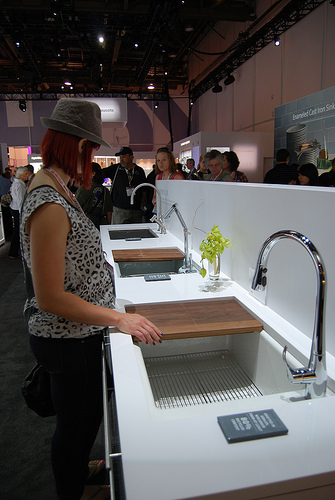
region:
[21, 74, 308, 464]
people standing among displays at convention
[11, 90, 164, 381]
woman leaning against white counter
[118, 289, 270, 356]
hand on wooden cutting board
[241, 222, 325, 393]
neck of curved silver faucet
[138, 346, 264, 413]
metal grid at bottom of sink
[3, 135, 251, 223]
convention attendees close together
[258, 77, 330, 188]
people in front of large poster on wall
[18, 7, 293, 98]
lights and supporting structures on ceiling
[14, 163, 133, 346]
woman in animal-print blouse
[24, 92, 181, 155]
lighted panel on elevated wall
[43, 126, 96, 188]
bold red hair on a woman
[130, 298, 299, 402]
an open sink display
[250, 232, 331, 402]
a large curved metal sink faucet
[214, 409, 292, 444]
a grey and white book on the counter top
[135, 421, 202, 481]
the white sink display counter top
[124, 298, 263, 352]
the woman's hand resting on a wooden sliding block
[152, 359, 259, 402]
a metal draining board in the sink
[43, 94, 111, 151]
a grey fedora on a woman's head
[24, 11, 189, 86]
black metal light fixtures on the ceiling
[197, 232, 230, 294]
a green plant in a glass of water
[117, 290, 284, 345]
Brown wood on a sink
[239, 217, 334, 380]
Silver faucet on a sink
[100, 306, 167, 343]
Woman's hand on a piece of wood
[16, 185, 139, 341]
Cheeta print on a shirt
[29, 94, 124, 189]
Hat on a woman's head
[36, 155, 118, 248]
Necklace on a woman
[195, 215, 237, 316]
Plant on a counter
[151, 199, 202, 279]
Silver faucet on a sink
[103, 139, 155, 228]
Man in a black hat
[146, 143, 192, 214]
Woman in a red shirt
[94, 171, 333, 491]
a kitchen sink display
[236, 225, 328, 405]
a chrome kitchen sink faucet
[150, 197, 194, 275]
a chrome kitchen sink faucet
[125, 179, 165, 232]
a chrome kitchen sink faucet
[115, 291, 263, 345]
a wooden cutting board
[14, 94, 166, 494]
a woman with red hair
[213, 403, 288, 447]
a countertop mounted sign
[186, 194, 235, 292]
a clear vase with greenery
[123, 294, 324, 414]
a kitchen sink basin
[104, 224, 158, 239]
a kitchen sink basin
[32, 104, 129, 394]
a beautiful women standing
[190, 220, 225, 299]
a beautiful flower pot placed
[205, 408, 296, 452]
a small diary placed on table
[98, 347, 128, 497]
a iron rod connected to table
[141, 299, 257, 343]
a wooden block is placed on table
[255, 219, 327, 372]
a washer to wash hands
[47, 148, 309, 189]
a group of people watching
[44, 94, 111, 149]
cap of the women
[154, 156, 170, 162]
a beautiful white lady eyes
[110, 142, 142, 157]
a small cap of a men